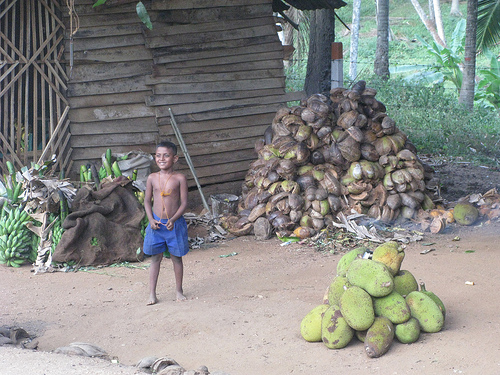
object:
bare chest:
[149, 171, 179, 208]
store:
[2, 2, 294, 219]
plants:
[392, 57, 499, 150]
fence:
[276, 0, 499, 152]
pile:
[300, 241, 444, 357]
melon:
[300, 305, 325, 341]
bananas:
[10, 182, 23, 202]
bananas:
[10, 207, 15, 220]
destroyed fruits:
[213, 86, 456, 240]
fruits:
[344, 257, 395, 297]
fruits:
[371, 240, 404, 276]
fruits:
[404, 291, 445, 334]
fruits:
[338, 286, 375, 332]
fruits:
[362, 314, 396, 358]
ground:
[1, 262, 143, 375]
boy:
[142, 141, 187, 306]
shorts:
[145, 204, 197, 264]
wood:
[57, 2, 292, 209]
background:
[261, 49, 306, 92]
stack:
[89, 23, 262, 140]